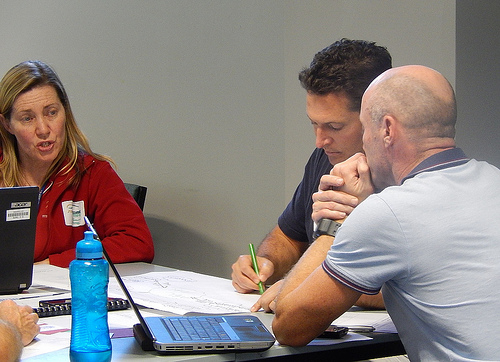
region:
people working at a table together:
[6, 36, 481, 328]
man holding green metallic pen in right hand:
[231, 239, 278, 303]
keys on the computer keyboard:
[174, 315, 216, 340]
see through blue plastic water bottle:
[65, 225, 120, 357]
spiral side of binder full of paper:
[27, 294, 136, 317]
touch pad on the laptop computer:
[231, 317, 263, 344]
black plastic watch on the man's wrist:
[307, 210, 349, 246]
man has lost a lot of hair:
[351, 57, 470, 161]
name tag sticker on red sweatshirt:
[52, 190, 93, 238]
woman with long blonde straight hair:
[5, 58, 96, 221]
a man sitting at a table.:
[220, 32, 402, 316]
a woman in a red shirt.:
[1, 56, 161, 292]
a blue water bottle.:
[60, 218, 118, 359]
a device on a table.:
[126, 301, 288, 358]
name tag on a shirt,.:
[54, 196, 93, 233]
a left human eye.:
[41, 96, 63, 129]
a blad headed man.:
[349, 58, 471, 181]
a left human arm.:
[234, 231, 373, 352]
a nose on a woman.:
[27, 125, 54, 139]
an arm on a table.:
[1, 293, 53, 359]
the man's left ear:
[376, 116, 401, 148]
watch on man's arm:
[315, 216, 340, 236]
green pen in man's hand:
[248, 239, 267, 292]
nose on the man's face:
[314, 125, 330, 150]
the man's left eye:
[324, 122, 343, 133]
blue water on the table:
[71, 229, 111, 358]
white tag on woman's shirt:
[62, 195, 85, 228]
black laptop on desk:
[1, 187, 37, 296]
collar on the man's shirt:
[399, 151, 469, 172]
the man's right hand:
[231, 251, 278, 292]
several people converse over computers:
[1, 28, 493, 355]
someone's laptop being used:
[78, 204, 279, 356]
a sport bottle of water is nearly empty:
[62, 226, 119, 360]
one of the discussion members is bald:
[264, 59, 497, 359]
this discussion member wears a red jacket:
[1, 56, 160, 273]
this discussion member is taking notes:
[226, 26, 402, 299]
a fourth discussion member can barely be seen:
[1, 288, 48, 360]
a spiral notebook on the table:
[2, 284, 142, 321]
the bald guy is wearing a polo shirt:
[319, 141, 498, 360]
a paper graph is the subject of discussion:
[21, 254, 394, 331]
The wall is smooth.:
[124, 33, 229, 98]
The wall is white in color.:
[133, 22, 264, 112]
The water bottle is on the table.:
[64, 227, 115, 359]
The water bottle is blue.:
[68, 226, 115, 358]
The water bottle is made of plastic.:
[63, 226, 115, 360]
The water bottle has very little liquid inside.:
[61, 225, 119, 360]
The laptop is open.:
[86, 212, 281, 357]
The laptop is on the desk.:
[85, 214, 281, 353]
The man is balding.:
[357, 62, 472, 189]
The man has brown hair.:
[287, 35, 398, 162]